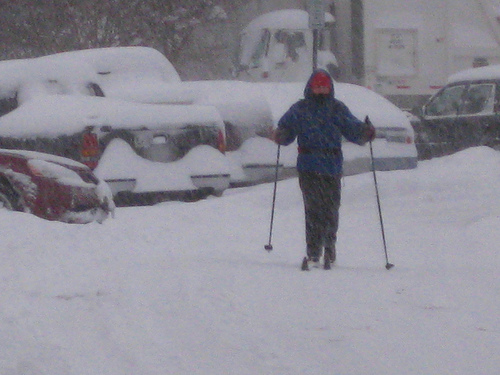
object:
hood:
[0, 149, 115, 225]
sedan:
[0, 148, 115, 224]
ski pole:
[368, 137, 393, 271]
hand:
[357, 115, 375, 145]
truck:
[0, 47, 229, 207]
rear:
[59, 102, 184, 169]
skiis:
[224, 205, 416, 294]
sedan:
[405, 79, 500, 160]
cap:
[310, 71, 331, 87]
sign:
[308, 0, 326, 30]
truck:
[179, 8, 416, 186]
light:
[81, 133, 98, 169]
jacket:
[276, 68, 367, 176]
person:
[271, 68, 376, 271]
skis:
[301, 256, 321, 271]